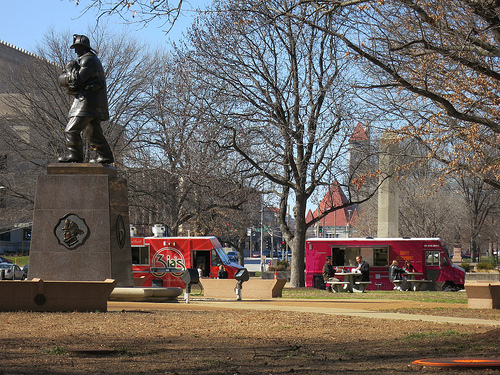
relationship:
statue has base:
[51, 37, 116, 169] [44, 176, 131, 301]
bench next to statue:
[0, 281, 108, 308] [32, 36, 122, 273]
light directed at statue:
[231, 266, 250, 302] [25, 33, 132, 293]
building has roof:
[310, 174, 350, 238] [317, 182, 349, 224]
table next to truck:
[322, 263, 372, 294] [302, 228, 466, 293]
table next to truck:
[389, 265, 432, 287] [302, 228, 466, 293]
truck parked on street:
[131, 238, 234, 282] [242, 269, 277, 277]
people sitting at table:
[323, 256, 373, 291] [331, 271, 360, 291]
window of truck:
[128, 245, 152, 267] [111, 224, 258, 285]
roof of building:
[306, 172, 351, 228] [304, 166, 355, 246]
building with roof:
[245, 162, 425, 258] [300, 172, 364, 230]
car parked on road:
[1, 264, 26, 281] [17, 255, 291, 280]